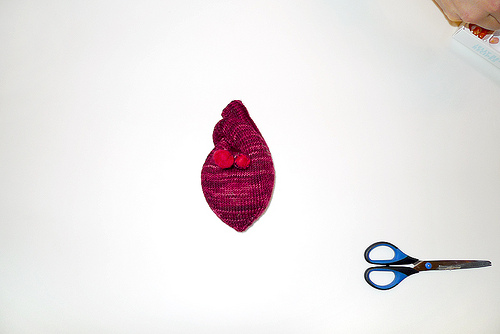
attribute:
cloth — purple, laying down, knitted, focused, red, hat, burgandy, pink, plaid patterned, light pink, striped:
[201, 100, 276, 233]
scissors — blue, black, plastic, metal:
[364, 241, 496, 291]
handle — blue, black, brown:
[364, 241, 416, 291]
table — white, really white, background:
[2, 1, 499, 333]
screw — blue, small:
[423, 261, 435, 270]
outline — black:
[364, 241, 419, 290]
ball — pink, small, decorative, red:
[211, 148, 236, 169]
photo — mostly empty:
[2, 1, 499, 333]